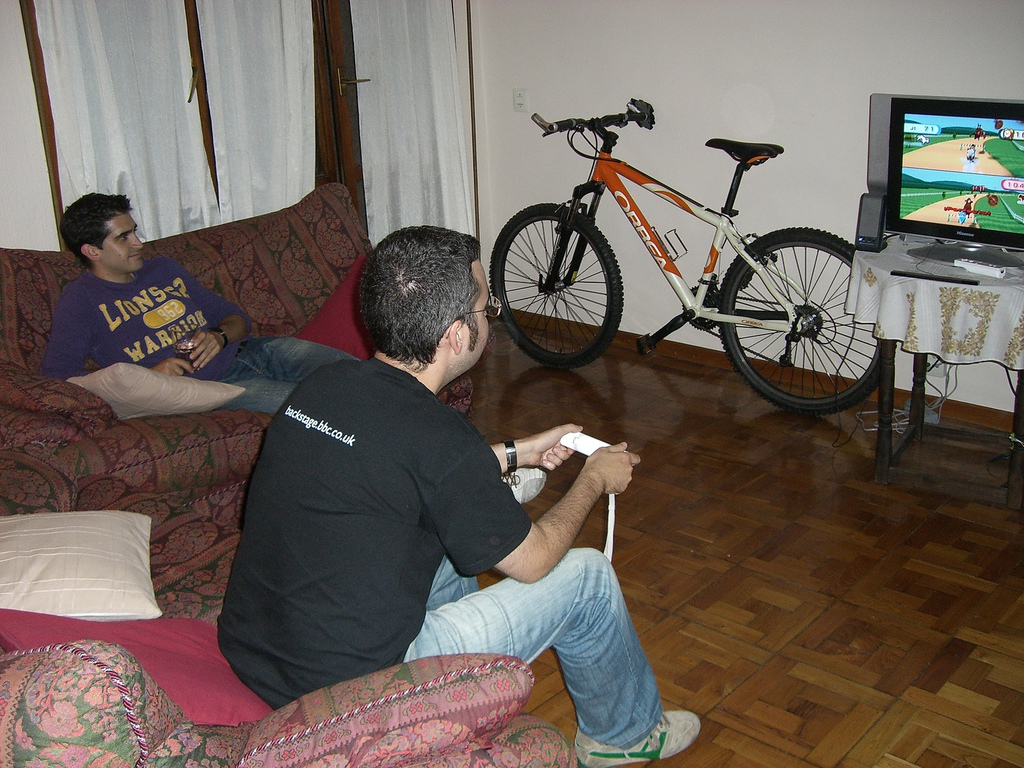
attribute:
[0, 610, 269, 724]
pillow — dark pink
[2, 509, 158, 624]
pillow — light pink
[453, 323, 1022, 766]
ground — brown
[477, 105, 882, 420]
object — orange, white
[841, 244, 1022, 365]
table cloth — white, gold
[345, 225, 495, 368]
black hair — short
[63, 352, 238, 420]
pillow — beige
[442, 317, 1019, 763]
floor — brown, shiny